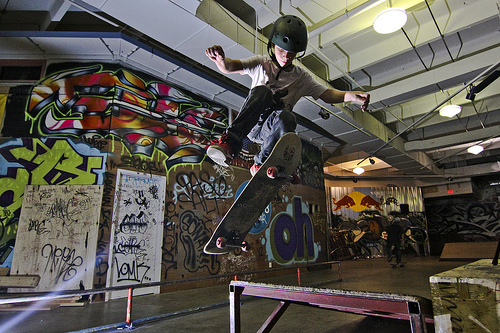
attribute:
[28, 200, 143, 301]
graffiti — black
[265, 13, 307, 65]
helmet — black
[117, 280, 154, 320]
rail — small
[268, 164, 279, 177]
wheel — red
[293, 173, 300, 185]
wheel — red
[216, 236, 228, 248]
wheel — red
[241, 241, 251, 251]
wheel — red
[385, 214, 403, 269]
person — walking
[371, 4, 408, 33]
light — ceiling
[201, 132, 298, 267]
skateboard — worn, wooden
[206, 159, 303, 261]
wheels — red, skateboard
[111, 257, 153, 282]
graffiti — very good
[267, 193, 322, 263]
graffiti — very good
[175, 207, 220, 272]
graffiti — very good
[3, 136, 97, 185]
graffiti — very good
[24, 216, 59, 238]
graffiti — very good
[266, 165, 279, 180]
wheels — red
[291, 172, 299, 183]
wheels — red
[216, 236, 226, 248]
wheels — red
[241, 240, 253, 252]
wheels — red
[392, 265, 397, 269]
wheels — red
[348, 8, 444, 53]
light fixtures — on, overhead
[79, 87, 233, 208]
walls — spray painted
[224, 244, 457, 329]
ramp — small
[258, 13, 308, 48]
helmet — green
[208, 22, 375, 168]
skater — crouched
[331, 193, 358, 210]
logo — red, yellow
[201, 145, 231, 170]
shoe — red, white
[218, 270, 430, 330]
ramp — wooden, skateboard, red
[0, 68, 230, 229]
graffiti — painted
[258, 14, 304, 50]
helmet — black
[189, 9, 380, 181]
boy — skateboarding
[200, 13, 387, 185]
kid — young